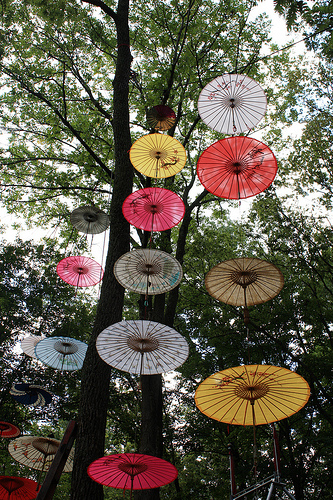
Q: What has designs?
A: This umbrella.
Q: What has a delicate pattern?
A: The umbrella.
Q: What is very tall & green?
A: The trees.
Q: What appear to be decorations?
A: All the umbrellas.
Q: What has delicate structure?
A: The umbrellas.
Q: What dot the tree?
A: Many japanese umbrellas.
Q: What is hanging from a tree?
A: Small umbrellas.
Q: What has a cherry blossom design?
A: A yellow umbrella.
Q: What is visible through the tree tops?
A: Clouds.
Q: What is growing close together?
A: Two trees.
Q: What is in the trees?
A: Umbrellas.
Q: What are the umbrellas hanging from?
A: Trees.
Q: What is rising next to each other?
A: Two tree trunks.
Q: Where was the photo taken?
A: In woods.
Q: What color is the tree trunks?
A: Brown.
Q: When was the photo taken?
A: Daytime.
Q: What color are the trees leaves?
A: Green.